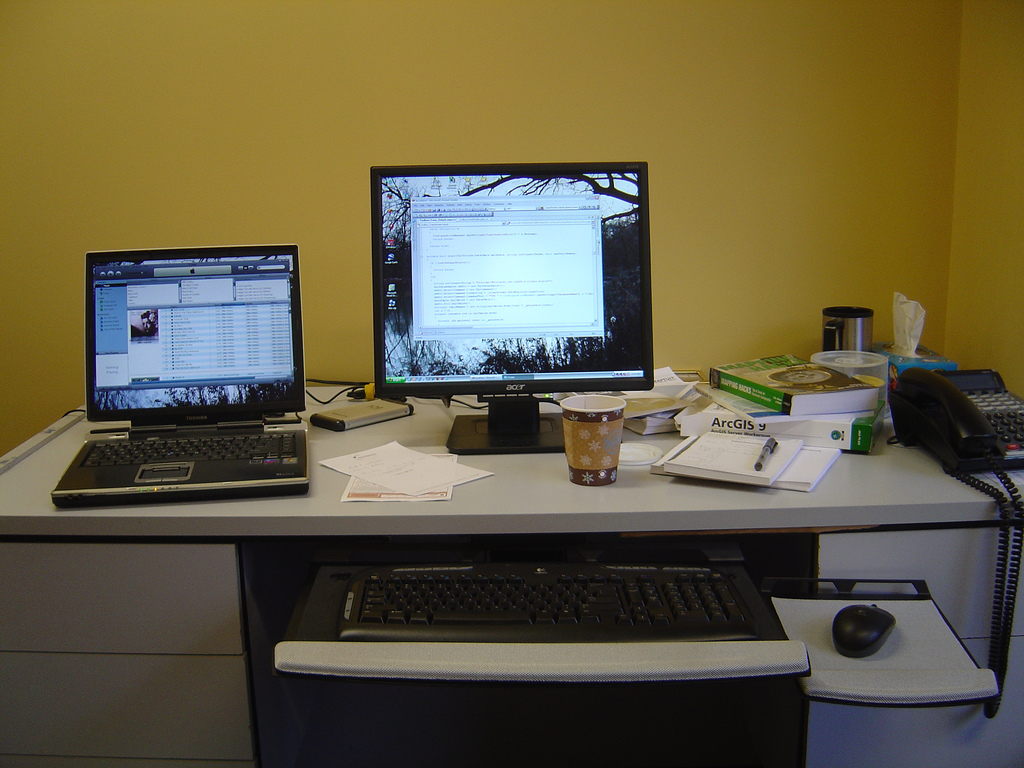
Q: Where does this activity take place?
A: At work.